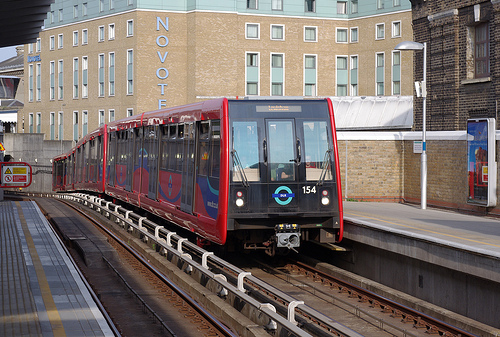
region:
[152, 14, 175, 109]
name of this building in powder blue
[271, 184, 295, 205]
logo of the tram company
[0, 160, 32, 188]
warning sign on a red painted gate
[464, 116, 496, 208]
case with safety glass holding an axe and fire extinguisher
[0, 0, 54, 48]
aluminum over hang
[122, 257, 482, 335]
railroad tracks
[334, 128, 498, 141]
white cement top of a brick wall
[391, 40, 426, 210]
shiney silver light post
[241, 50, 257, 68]
window with an open curtain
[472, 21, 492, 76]
brown trimmed window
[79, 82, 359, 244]
red and black train on a track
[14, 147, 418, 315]
train track with a train on it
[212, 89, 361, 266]
the front of the train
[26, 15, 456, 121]
a brick building in the background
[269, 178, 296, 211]
blue circle on front of the train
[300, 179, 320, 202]
the number one five four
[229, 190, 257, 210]
the left headlight of the train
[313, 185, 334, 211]
the right headlight of the train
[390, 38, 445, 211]
street light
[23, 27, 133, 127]
windows on the side of the building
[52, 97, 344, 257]
A train driving down the tracks.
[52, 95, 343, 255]
the long train on the track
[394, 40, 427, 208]
the silver light pole on the sidewalk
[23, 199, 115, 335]
the white line on the walk way near the train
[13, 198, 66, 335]
the yellow line on the walk way near the train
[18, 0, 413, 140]
the brown and blue wall in the back of the train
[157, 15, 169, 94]
the letters "NOVOT" on the side of the building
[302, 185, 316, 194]
the numbers "154" on the front of the train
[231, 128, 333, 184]
the wind shield wipers on the front of the train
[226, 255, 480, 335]
the track on the ground in front of the train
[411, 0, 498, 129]
the brown brick building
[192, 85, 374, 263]
red and black train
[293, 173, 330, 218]
train's number is 154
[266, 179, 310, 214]
blue and turquoise emblem on the train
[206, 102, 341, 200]
train has three large front windows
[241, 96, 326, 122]
train has orange neon sign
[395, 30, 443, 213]
lamp post on the platform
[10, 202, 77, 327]
yellow line on the platform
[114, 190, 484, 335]
the train tracks are metal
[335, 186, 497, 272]
the platform is concrete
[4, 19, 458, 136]
building in the background